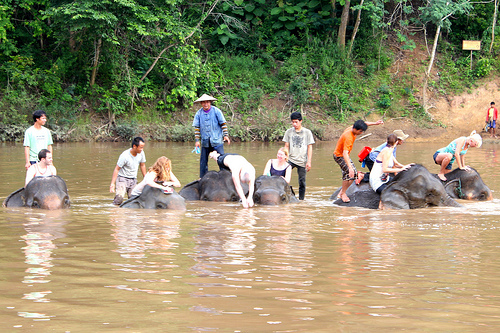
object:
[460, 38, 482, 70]
sign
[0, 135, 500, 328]
river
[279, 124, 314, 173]
shirt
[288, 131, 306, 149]
design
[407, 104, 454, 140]
wall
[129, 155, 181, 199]
girl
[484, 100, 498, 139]
kid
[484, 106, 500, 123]
jacket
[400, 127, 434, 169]
ground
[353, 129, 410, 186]
people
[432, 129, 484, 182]
girl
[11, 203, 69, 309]
reflection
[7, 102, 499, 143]
shore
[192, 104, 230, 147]
blue shirt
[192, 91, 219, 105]
hat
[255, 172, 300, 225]
elephant water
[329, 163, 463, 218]
elephant water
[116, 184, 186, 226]
elephant water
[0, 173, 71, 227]
elephant water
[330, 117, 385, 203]
boy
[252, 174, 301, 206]
elephant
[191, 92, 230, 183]
people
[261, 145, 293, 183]
women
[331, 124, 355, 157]
orange shirt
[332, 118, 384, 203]
guy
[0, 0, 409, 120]
trees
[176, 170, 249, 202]
elephant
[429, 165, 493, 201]
elephant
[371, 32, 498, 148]
dirt-covered hillside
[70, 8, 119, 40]
leaves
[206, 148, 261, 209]
man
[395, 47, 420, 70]
dirt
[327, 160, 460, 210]
elephant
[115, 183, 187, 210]
elephant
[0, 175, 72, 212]
elephant